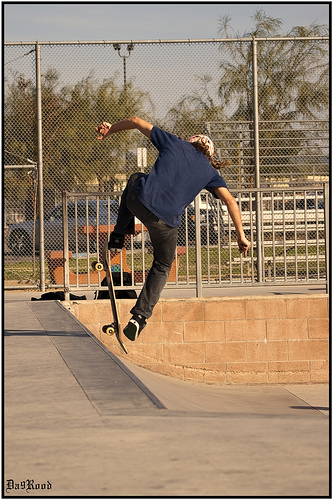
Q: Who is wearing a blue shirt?
A: Skateboarder.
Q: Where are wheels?
A: On the skateboard.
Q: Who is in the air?
A: Skateboarder.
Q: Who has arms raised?
A: The skateboarder.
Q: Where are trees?
A: In the distance.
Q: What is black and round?
A: Car tires.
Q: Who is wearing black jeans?
A: Guy skateboarding.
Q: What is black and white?
A: Sneakers.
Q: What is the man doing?
A: Skateboarding.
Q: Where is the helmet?
A: On the man's head.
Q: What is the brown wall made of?
A: Stone bricks.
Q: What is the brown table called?
A: Picnic table.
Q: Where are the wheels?
A: On the bottom of the skateboard.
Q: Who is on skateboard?
A: Person with long hair.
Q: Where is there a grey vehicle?
A: In background.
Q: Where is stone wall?
A: On skate ramp.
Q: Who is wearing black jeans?
A: The man.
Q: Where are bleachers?
A: In background of photo.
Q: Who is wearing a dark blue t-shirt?
A: The man.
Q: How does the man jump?
A: On a ramp.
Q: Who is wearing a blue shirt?
A: The man.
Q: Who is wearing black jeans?
A: The man.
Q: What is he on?
A: The ramp.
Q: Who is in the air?
A: The guy.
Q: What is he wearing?
A: Jeans.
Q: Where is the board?
A: In the air.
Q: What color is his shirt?
A: Blue.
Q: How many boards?
A: 1.